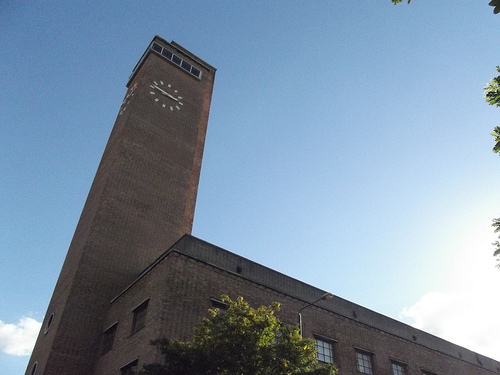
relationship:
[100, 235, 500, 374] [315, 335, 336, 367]
building has windows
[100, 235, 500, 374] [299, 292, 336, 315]
building has lamp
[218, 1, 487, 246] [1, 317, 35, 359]
sky has a cloud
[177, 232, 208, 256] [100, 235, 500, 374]
roof of building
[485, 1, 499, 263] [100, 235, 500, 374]
tree by building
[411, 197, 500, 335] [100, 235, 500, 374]
sun glare behind building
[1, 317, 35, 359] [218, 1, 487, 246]
one cloud in sky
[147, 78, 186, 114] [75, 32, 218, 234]
clock on tower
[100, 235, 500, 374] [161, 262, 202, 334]
building made of bricks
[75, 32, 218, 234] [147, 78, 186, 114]
tower has a clock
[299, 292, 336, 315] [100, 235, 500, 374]
street light on building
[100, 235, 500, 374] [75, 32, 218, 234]
building part of clock tower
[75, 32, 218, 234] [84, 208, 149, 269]
clock tower made of brick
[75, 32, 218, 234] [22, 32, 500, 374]
tower visible from a distance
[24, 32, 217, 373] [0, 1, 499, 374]
tower visible for miles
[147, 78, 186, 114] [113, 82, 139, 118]
clock on all sides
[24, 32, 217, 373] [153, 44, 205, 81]
tower has windows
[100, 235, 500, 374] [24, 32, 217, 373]
brick building with a tower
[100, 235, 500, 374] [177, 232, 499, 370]
building has a roof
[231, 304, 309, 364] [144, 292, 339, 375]
leaves on trees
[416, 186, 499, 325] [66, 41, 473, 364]
sunlight in corner of building